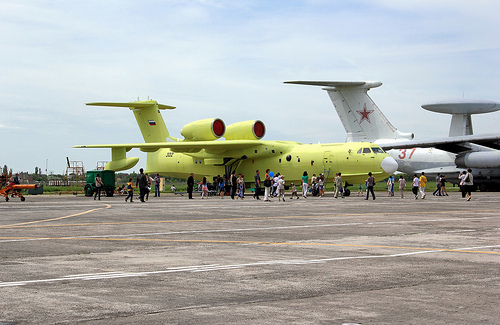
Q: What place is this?
A: It is an airport.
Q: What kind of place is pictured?
A: It is an airport.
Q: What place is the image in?
A: It is at the airport.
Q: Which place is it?
A: It is an airport.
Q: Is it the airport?
A: Yes, it is the airport.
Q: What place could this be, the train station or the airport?
A: It is the airport.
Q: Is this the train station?
A: No, it is the airport.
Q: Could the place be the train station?
A: No, it is the airport.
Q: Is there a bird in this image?
A: No, there are no birds.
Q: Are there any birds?
A: No, there are no birds.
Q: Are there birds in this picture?
A: No, there are no birds.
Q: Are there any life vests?
A: No, there are no life vests.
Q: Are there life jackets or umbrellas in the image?
A: No, there are no life jackets or umbrellas.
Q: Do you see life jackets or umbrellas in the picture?
A: No, there are no life jackets or umbrellas.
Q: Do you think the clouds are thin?
A: Yes, the clouds are thin.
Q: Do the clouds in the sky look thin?
A: Yes, the clouds are thin.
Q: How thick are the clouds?
A: The clouds are thin.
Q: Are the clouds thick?
A: No, the clouds are thin.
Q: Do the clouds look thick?
A: No, the clouds are thin.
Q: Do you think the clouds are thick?
A: No, the clouds are thin.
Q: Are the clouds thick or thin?
A: The clouds are thin.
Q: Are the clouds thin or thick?
A: The clouds are thin.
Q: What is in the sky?
A: The clouds are in the sky.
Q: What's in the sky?
A: The clouds are in the sky.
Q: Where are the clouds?
A: The clouds are in the sky.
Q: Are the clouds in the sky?
A: Yes, the clouds are in the sky.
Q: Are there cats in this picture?
A: No, there are no cats.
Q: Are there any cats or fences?
A: No, there are no cats or fences.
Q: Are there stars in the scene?
A: Yes, there is a star.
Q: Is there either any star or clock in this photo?
A: Yes, there is a star.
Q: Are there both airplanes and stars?
A: Yes, there are both a star and an airplane.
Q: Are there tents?
A: No, there are no tents.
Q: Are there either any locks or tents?
A: No, there are no tents or locks.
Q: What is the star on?
A: The star is on the airplane.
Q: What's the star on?
A: The star is on the airplane.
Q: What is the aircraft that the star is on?
A: The aircraft is an airplane.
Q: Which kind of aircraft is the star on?
A: The star is on the airplane.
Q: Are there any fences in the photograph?
A: No, there are no fences.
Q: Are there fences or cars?
A: No, there are no fences or cars.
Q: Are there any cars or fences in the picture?
A: No, there are no fences or cars.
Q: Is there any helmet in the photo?
A: No, there are no helmets.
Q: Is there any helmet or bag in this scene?
A: No, there are no helmets or bags.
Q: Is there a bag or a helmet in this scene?
A: No, there are no helmets or bags.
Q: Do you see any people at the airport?
A: Yes, there is a person at the airport.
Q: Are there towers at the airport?
A: No, there is a person at the airport.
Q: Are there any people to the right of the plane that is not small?
A: Yes, there is a person to the right of the airplane.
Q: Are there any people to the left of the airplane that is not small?
A: No, the person is to the right of the airplane.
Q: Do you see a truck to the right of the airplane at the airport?
A: No, there is a person to the right of the plane.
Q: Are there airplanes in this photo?
A: Yes, there is an airplane.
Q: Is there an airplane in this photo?
A: Yes, there is an airplane.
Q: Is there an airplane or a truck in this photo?
A: Yes, there is an airplane.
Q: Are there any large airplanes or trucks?
A: Yes, there is a large airplane.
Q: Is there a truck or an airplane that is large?
A: Yes, the airplane is large.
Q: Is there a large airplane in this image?
A: Yes, there is a large airplane.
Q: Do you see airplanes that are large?
A: Yes, there is a large airplane.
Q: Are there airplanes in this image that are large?
A: Yes, there is an airplane that is large.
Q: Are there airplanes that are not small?
A: Yes, there is a large airplane.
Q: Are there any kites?
A: No, there are no kites.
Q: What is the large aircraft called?
A: The aircraft is an airplane.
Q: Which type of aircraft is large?
A: The aircraft is an airplane.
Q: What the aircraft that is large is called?
A: The aircraft is an airplane.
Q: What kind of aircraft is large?
A: The aircraft is an airplane.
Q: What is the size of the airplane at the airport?
A: The airplane is large.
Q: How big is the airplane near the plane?
A: The plane is large.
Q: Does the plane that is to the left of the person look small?
A: No, the airplane is large.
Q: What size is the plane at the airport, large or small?
A: The airplane is large.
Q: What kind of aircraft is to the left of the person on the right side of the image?
A: The aircraft is an airplane.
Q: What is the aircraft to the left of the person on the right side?
A: The aircraft is an airplane.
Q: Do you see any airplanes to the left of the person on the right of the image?
A: Yes, there is an airplane to the left of the person.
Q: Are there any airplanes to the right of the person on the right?
A: No, the airplane is to the left of the person.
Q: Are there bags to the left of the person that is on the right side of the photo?
A: No, there is an airplane to the left of the person.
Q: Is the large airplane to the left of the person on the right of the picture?
A: Yes, the airplane is to the left of the person.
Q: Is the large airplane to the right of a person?
A: No, the airplane is to the left of a person.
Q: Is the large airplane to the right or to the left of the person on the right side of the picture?
A: The airplane is to the left of the person.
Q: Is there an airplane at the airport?
A: Yes, there is an airplane at the airport.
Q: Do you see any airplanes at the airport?
A: Yes, there is an airplane at the airport.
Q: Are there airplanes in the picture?
A: Yes, there is an airplane.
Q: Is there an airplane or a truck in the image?
A: Yes, there is an airplane.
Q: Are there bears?
A: No, there are no bears.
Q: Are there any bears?
A: No, there are no bears.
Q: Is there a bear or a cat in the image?
A: No, there are no bears or cats.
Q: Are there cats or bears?
A: No, there are no bears or cats.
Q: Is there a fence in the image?
A: No, there are no fences.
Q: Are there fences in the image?
A: No, there are no fences.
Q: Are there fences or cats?
A: No, there are no fences or cats.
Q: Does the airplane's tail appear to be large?
A: Yes, the tail is large.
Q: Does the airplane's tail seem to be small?
A: No, the tail is large.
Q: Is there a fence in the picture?
A: No, there are no fences.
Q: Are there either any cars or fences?
A: No, there are no fences or cars.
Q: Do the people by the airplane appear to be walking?
A: Yes, the people are walking.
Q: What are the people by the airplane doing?
A: The people are walking.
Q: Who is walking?
A: The people are walking.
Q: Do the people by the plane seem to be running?
A: No, the people are walking.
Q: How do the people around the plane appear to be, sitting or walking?
A: The people are walking.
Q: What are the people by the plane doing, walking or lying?
A: The people are walking.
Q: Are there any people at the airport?
A: Yes, there are people at the airport.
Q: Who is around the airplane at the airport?
A: The people are around the airplane.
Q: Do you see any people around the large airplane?
A: Yes, there are people around the plane.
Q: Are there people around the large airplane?
A: Yes, there are people around the plane.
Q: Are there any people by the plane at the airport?
A: Yes, there are people by the airplane.